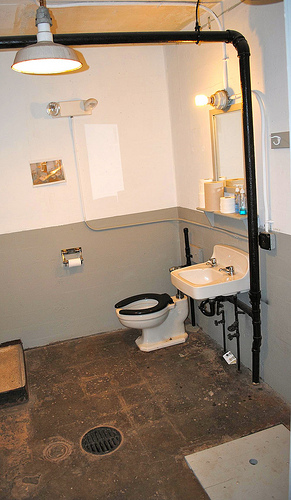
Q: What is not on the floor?
A: Tile.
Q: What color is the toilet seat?
A: Black.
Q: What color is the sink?
A: White.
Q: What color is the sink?
A: White.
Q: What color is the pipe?
A: Black.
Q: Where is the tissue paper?
A: Stand.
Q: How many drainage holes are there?
A: One.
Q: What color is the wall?
A: Grey and white.